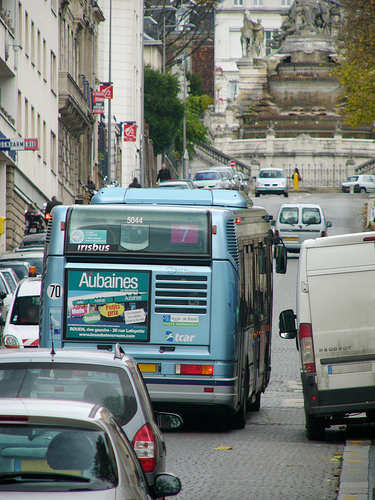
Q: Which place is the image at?
A: It is at the street.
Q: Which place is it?
A: It is a street.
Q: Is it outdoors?
A: Yes, it is outdoors.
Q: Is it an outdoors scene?
A: Yes, it is outdoors.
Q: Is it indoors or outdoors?
A: It is outdoors.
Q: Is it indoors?
A: No, it is outdoors.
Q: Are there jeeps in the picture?
A: No, there are no jeeps.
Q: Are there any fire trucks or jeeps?
A: No, there are no jeeps or fire trucks.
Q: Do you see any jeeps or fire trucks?
A: No, there are no jeeps or fire trucks.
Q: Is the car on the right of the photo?
A: Yes, the car is on the right of the image.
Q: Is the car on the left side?
A: No, the car is on the right of the image.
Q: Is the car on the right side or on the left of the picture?
A: The car is on the right of the image.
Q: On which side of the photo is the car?
A: The car is on the right of the image.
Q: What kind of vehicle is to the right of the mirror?
A: The vehicle is a car.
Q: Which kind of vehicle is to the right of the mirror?
A: The vehicle is a car.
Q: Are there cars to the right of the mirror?
A: Yes, there is a car to the right of the mirror.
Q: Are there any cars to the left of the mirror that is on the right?
A: No, the car is to the right of the mirror.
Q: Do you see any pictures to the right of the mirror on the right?
A: No, there is a car to the right of the mirror.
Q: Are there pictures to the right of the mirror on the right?
A: No, there is a car to the right of the mirror.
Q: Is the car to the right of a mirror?
A: Yes, the car is to the right of a mirror.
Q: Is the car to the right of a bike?
A: No, the car is to the right of a mirror.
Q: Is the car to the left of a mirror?
A: No, the car is to the right of a mirror.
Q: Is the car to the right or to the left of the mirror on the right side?
A: The car is to the right of the mirror.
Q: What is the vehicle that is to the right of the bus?
A: The vehicle is a car.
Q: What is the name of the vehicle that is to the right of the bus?
A: The vehicle is a car.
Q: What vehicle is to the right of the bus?
A: The vehicle is a car.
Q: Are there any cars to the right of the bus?
A: Yes, there is a car to the right of the bus.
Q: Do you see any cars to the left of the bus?
A: No, the car is to the right of the bus.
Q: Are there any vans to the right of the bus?
A: No, there is a car to the right of the bus.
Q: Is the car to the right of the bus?
A: Yes, the car is to the right of the bus.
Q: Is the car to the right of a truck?
A: No, the car is to the right of the bus.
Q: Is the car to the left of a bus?
A: No, the car is to the right of a bus.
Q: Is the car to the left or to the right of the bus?
A: The car is to the right of the bus.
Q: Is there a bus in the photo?
A: Yes, there is a bus.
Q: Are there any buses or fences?
A: Yes, there is a bus.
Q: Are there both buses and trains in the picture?
A: No, there is a bus but no trains.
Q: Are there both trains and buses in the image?
A: No, there is a bus but no trains.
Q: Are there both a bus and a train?
A: No, there is a bus but no trains.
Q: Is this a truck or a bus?
A: This is a bus.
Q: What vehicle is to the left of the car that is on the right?
A: The vehicle is a bus.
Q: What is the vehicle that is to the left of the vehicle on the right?
A: The vehicle is a bus.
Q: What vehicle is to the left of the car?
A: The vehicle is a bus.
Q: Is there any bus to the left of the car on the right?
A: Yes, there is a bus to the left of the car.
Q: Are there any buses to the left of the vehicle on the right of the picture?
A: Yes, there is a bus to the left of the car.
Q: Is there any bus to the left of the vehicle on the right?
A: Yes, there is a bus to the left of the car.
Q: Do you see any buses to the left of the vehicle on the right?
A: Yes, there is a bus to the left of the car.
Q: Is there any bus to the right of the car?
A: No, the bus is to the left of the car.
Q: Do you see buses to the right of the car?
A: No, the bus is to the left of the car.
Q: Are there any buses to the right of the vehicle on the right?
A: No, the bus is to the left of the car.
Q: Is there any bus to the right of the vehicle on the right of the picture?
A: No, the bus is to the left of the car.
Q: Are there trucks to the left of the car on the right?
A: No, there is a bus to the left of the car.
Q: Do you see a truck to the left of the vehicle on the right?
A: No, there is a bus to the left of the car.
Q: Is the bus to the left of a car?
A: Yes, the bus is to the left of a car.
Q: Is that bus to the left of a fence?
A: No, the bus is to the left of a car.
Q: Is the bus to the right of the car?
A: No, the bus is to the left of the car.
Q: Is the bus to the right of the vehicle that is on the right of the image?
A: No, the bus is to the left of the car.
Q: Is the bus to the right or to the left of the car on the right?
A: The bus is to the left of the car.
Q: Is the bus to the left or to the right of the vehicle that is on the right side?
A: The bus is to the left of the car.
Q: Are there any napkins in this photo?
A: No, there are no napkins.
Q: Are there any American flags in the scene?
A: No, there are no American flags.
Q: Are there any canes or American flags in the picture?
A: No, there are no American flags or canes.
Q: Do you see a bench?
A: No, there are no benches.